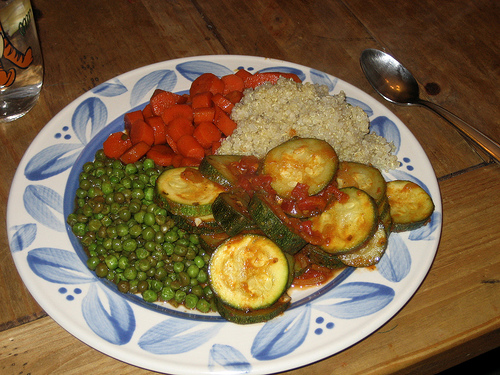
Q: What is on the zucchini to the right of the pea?
A: The sauce is on the zucchini.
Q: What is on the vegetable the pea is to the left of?
A: The sauce is on the zucchini.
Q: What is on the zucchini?
A: The sauce is on the zucchini.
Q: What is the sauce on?
A: The sauce is on the zucchini.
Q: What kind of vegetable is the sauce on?
A: The sauce is on the zucchini.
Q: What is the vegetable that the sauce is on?
A: The vegetable is a zucchini.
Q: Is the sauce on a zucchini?
A: Yes, the sauce is on a zucchini.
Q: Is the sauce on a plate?
A: No, the sauce is on a zucchini.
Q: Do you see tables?
A: Yes, there is a table.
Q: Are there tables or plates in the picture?
A: Yes, there is a table.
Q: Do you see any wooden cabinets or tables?
A: Yes, there is a wood table.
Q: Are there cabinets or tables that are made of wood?
A: Yes, the table is made of wood.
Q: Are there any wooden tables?
A: Yes, there is a wood table.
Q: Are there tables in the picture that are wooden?
A: Yes, there is a table that is wooden.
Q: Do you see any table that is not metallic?
A: Yes, there is a wooden table.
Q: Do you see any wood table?
A: Yes, there is a table that is made of wood.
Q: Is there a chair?
A: No, there are no chairs.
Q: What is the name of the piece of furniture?
A: The piece of furniture is a table.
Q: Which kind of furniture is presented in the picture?
A: The furniture is a table.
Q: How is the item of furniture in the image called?
A: The piece of furniture is a table.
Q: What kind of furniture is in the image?
A: The furniture is a table.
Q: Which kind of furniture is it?
A: The piece of furniture is a table.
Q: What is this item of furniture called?
A: This is a table.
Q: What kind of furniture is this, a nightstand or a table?
A: This is a table.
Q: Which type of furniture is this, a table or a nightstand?
A: This is a table.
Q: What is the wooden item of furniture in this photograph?
A: The piece of furniture is a table.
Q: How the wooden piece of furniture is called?
A: The piece of furniture is a table.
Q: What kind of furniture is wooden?
A: The furniture is a table.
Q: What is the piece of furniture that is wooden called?
A: The piece of furniture is a table.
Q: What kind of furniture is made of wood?
A: The furniture is a table.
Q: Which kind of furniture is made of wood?
A: The furniture is a table.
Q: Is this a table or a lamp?
A: This is a table.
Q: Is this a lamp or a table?
A: This is a table.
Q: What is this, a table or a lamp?
A: This is a table.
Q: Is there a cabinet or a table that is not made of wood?
A: No, there is a table but it is made of wood.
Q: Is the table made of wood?
A: Yes, the table is made of wood.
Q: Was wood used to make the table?
A: Yes, the table is made of wood.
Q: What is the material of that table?
A: The table is made of wood.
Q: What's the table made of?
A: The table is made of wood.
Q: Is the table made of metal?
A: No, the table is made of wood.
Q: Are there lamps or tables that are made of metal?
A: No, there is a table but it is made of wood.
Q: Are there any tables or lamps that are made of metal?
A: No, there is a table but it is made of wood.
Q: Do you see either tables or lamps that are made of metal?
A: No, there is a table but it is made of wood.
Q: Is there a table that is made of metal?
A: No, there is a table but it is made of wood.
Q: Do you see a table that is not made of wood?
A: No, there is a table but it is made of wood.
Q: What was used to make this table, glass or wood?
A: The table is made of wood.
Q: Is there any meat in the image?
A: No, there is no meat.